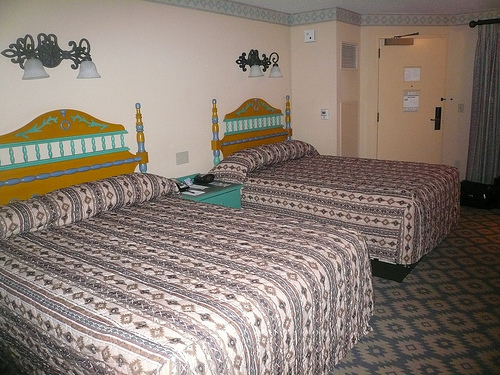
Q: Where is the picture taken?
A: Hotel room.